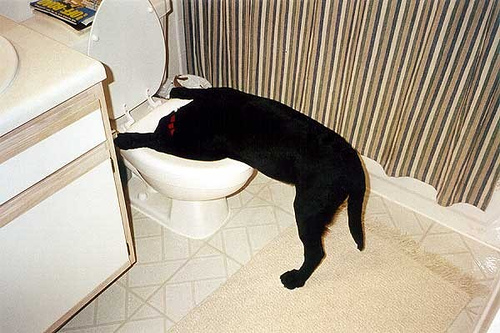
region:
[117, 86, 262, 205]
dogs head in toilet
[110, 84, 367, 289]
dog is very black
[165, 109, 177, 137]
dog is wearing collar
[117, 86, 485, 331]
dog is standing on rug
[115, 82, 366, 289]
dog's paws on toilet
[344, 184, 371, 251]
dog's tail is down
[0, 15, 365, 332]
dog is next to sink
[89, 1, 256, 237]
toilet seat is up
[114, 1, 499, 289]
dog near shower curtain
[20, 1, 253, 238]
magazines on top of toilet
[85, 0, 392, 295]
BLACK CAT DRINKING OUT OF THE TOILET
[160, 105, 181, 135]
RED CAT COLLAR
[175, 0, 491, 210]
STRIPPED SHOWER CURTAIN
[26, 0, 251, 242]
A WHITE TOILET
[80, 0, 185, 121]
WHITE TOILET SEAT LID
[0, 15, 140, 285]
WHITE BATHROOM SINK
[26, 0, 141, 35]
MAGAZINES ON THE TOILET TANK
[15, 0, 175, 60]
TOILET TANK COVER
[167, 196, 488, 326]
A THROW RUG ON THE BATHROOM FLOOR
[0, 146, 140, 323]
BATHROOM SINK CABINET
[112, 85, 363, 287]
shiny black dog that appears sick.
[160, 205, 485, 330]
clean beige floor rug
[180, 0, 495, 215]
long striped curtain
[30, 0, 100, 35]
magazines on top of toilet tank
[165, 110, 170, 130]
red dog collar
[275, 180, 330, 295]
hind leg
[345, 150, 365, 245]
dog tail that is not wagging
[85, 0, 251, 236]
open white toilet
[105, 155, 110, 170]
bathroom vanity door hinge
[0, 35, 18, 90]
corner of white sink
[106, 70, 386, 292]
Black dog in a bathroon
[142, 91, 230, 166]
Dog with head in toilet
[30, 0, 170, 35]
Magazines over the toilet tank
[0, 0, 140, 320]
Counter of sink is tan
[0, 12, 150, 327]
Counter of sink has white drowers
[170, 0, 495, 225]
Curtain of bathtub is striped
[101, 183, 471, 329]
Floor of bathroom is made of tiles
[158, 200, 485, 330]
Mat is light brown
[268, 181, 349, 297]
Back legs of dog on mat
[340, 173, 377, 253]
Tail of dog is down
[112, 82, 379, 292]
Black dog in bathroom.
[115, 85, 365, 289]
Black dog drinking out of toilet.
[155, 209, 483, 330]
Small beige bathroom rug.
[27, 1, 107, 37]
Magazines on the toilet top.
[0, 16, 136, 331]
Bathroom sink and cabinet.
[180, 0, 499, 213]
Vertical stripped bathroom curtains.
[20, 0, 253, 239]
White porcelain toilet.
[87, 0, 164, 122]
Toilet lid in the up position.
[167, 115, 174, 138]
Red dog collar.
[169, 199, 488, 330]
Beige fringed bathroom mat.